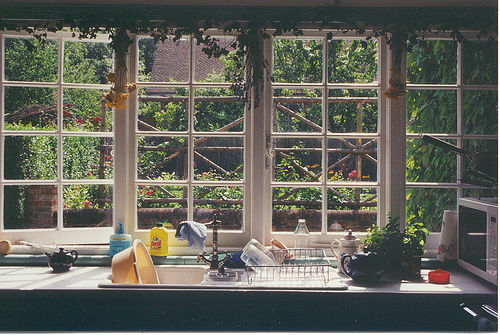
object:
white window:
[271, 34, 381, 241]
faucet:
[175, 220, 215, 238]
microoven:
[457, 196, 499, 286]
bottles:
[240, 245, 277, 276]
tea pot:
[45, 247, 78, 272]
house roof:
[142, 34, 239, 93]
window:
[132, 32, 252, 249]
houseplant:
[362, 217, 431, 281]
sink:
[107, 267, 205, 285]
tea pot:
[341, 251, 385, 283]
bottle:
[149, 223, 168, 256]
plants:
[0, 10, 498, 112]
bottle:
[109, 222, 131, 256]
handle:
[196, 251, 211, 267]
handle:
[218, 250, 233, 266]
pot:
[384, 254, 422, 279]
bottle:
[293, 218, 310, 257]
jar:
[330, 230, 360, 274]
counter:
[0, 265, 500, 333]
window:
[402, 37, 497, 249]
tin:
[428, 269, 450, 284]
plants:
[4, 38, 495, 231]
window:
[1, 28, 115, 245]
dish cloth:
[178, 221, 207, 250]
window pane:
[64, 87, 115, 132]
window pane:
[3, 85, 59, 130]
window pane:
[3, 183, 58, 228]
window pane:
[63, 185, 113, 226]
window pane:
[62, 136, 113, 179]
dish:
[245, 247, 331, 284]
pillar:
[23, 184, 58, 229]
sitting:
[335, 242, 405, 285]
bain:
[112, 239, 160, 283]